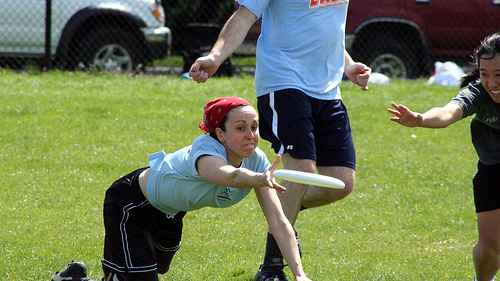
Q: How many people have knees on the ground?
A: One.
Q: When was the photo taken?
A: Day time.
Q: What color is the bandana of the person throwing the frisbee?
A: Red.